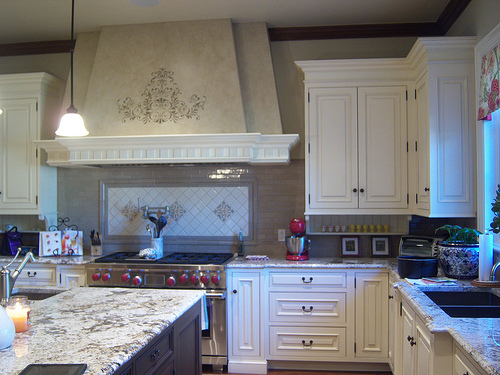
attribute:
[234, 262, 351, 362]
drawers — white, closed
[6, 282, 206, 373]
counter top — granite, black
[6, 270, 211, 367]
counter — marble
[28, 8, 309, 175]
vent — large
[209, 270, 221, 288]
knobs — red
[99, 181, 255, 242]
tiles — white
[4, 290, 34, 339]
candle — lit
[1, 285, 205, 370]
countertop — marble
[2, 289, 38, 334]
candle — on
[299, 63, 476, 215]
cupboards — white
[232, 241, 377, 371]
drawers — white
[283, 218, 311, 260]
electric mixer — red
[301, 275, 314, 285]
handles — black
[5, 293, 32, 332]
candle — lit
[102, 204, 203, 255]
fixture — stainless steel 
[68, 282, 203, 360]
marble counter — white, gray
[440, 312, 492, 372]
marble counter — white, gray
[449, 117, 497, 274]
light — natural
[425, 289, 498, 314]
basin — sink basin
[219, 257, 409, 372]
cabinets — white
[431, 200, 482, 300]
plant — potted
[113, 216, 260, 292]
stove — silver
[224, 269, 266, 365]
cupboard — White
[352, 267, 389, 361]
cupboard — White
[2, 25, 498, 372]
cabinets — white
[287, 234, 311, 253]
bowl — stainless steel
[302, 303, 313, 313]
handles — metal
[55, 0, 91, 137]
fixture — long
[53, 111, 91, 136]
light — on